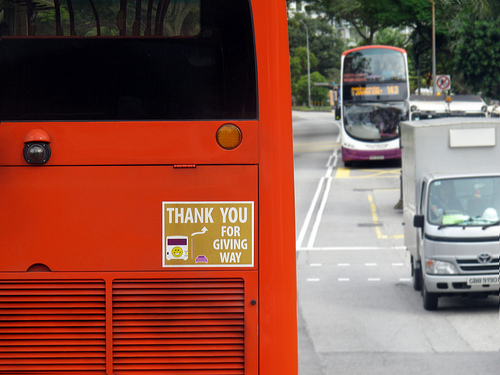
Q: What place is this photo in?
A: It is at the road.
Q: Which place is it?
A: It is a road.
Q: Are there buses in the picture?
A: Yes, there is a bus.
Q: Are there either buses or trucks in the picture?
A: Yes, there is a bus.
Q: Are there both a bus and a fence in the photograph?
A: No, there is a bus but no fences.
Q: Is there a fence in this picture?
A: No, there are no fences.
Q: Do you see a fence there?
A: No, there are no fences.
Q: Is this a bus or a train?
A: This is a bus.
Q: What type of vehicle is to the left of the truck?
A: The vehicle is a bus.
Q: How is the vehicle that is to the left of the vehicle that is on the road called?
A: The vehicle is a bus.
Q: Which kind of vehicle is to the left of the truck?
A: The vehicle is a bus.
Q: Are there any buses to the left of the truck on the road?
A: Yes, there is a bus to the left of the truck.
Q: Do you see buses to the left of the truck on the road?
A: Yes, there is a bus to the left of the truck.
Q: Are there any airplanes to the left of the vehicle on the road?
A: No, there is a bus to the left of the truck.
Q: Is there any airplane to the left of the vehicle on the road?
A: No, there is a bus to the left of the truck.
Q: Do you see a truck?
A: Yes, there is a truck.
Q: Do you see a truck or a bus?
A: Yes, there is a truck.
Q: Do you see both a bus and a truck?
A: Yes, there are both a truck and a bus.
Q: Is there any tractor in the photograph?
A: No, there are no tractors.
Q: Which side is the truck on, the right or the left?
A: The truck is on the right of the image.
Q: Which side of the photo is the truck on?
A: The truck is on the right of the image.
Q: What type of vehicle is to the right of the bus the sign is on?
A: The vehicle is a truck.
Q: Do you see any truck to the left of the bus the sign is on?
A: No, the truck is to the right of the bus.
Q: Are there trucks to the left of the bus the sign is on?
A: No, the truck is to the right of the bus.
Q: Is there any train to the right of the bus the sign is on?
A: No, there is a truck to the right of the bus.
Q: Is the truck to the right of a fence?
A: No, the truck is to the right of the bus.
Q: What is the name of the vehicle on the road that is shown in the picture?
A: The vehicle is a truck.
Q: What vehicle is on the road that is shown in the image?
A: The vehicle is a truck.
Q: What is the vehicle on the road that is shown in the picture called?
A: The vehicle is a truck.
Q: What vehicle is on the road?
A: The vehicle is a truck.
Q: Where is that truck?
A: The truck is on the road.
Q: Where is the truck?
A: The truck is on the road.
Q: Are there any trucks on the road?
A: Yes, there is a truck on the road.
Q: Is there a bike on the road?
A: No, there is a truck on the road.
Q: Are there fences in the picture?
A: No, there are no fences.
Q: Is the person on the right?
A: Yes, the person is on the right of the image.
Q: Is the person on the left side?
A: No, the person is on the right of the image.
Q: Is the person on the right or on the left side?
A: The person is on the right of the image.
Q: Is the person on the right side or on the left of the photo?
A: The person is on the right of the image.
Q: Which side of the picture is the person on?
A: The person is on the right of the image.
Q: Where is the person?
A: The person is in the truck.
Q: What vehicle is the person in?
A: The person is in the truck.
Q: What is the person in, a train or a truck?
A: The person is in a truck.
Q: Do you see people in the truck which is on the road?
A: Yes, there is a person in the truck.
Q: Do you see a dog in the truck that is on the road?
A: No, there is a person in the truck.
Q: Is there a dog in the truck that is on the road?
A: No, there is a person in the truck.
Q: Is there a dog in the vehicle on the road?
A: No, there is a person in the truck.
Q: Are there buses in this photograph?
A: Yes, there is a bus.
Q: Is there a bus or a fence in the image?
A: Yes, there is a bus.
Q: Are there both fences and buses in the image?
A: No, there is a bus but no fences.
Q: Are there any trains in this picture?
A: No, there are no trains.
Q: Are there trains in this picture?
A: No, there are no trains.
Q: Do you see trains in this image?
A: No, there are no trains.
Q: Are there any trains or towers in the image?
A: No, there are no trains or towers.